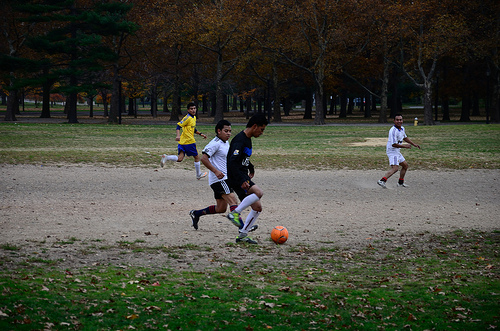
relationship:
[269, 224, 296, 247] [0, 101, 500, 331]
ball in area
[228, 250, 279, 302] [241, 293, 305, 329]
leave on grass